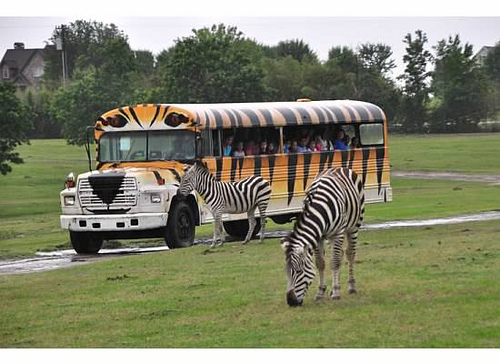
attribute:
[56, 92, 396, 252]
bus — driving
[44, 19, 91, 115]
pole — utility, in the background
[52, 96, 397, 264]
bus — yellow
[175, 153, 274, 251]
zebra — walking